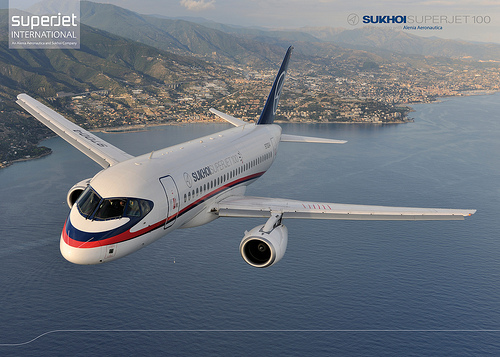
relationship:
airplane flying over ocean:
[21, 44, 479, 272] [0, 90, 498, 353]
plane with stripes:
[15, 45, 477, 268] [65, 169, 275, 251]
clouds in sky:
[178, 0, 213, 10] [101, 0, 499, 47]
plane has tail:
[15, 45, 477, 268] [256, 45, 296, 123]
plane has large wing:
[15, 45, 477, 268] [10, 90, 134, 167]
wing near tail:
[208, 105, 247, 125] [258, 46, 291, 124]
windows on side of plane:
[179, 146, 274, 213] [10, 72, 477, 269]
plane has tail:
[15, 45, 477, 268] [258, 46, 291, 124]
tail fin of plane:
[254, 40, 294, 125] [15, 45, 477, 268]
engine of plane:
[238, 222, 288, 268] [15, 45, 477, 268]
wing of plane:
[14, 90, 131, 164] [15, 45, 477, 268]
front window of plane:
[72, 186, 147, 216] [15, 45, 477, 268]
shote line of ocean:
[95, 115, 215, 133] [1, 128, 495, 355]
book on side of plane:
[158, 164, 187, 231] [39, 141, 389, 267]